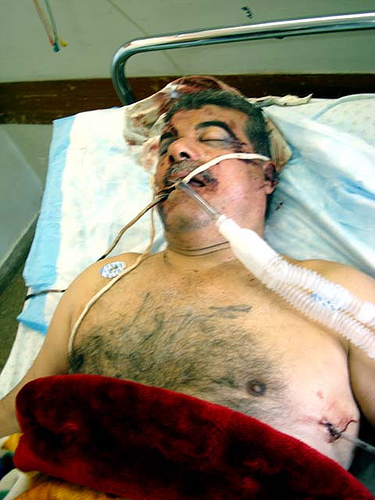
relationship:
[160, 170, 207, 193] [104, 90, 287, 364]
mouth of a man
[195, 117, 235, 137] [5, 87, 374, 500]
eyebrow of injured man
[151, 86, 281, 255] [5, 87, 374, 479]
head of injured man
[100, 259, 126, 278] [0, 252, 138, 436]
pads on arm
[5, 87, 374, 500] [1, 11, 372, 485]
injured man in hospital bed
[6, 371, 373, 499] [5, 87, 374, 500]
fabric on injured man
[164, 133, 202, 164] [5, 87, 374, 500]
nose on injured man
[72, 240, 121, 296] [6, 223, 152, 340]
electrical patch on shoulder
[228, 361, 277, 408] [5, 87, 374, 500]
nipple of injured man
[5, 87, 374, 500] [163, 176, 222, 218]
injured man has tube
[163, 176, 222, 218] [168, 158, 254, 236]
tube in mouth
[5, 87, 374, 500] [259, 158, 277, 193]
injured man has ear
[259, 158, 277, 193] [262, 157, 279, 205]
ear covered in blood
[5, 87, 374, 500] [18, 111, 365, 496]
injured man laying on hospital bed